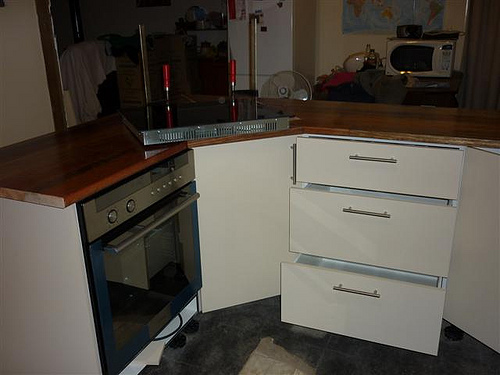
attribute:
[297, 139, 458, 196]
drawer — empty, open, white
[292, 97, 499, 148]
counter — wooden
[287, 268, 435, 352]
drawer — white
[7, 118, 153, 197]
counter — wooden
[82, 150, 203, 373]
oven — modern, black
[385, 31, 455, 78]
microwave — white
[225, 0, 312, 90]
refrdgerator — white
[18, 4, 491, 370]
kitchen — clean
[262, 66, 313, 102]
fan — small, white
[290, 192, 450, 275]
drawer — white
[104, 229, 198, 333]
door — glass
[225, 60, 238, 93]
handle — red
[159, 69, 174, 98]
handle — red